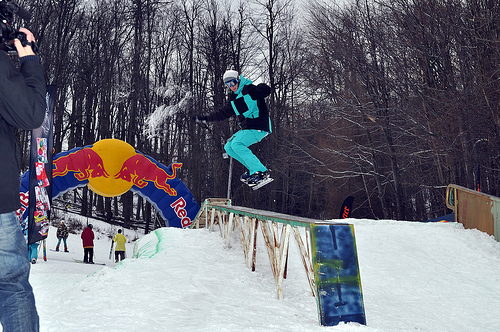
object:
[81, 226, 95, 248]
coat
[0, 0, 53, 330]
man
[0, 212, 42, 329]
jeans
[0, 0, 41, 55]
camera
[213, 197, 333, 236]
skateboarder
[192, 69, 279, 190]
man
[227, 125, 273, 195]
pants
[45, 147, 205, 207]
balloon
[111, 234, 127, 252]
coat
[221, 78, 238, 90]
glasses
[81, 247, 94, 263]
pants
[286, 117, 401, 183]
branches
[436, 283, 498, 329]
snow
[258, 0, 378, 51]
sky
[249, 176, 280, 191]
shadow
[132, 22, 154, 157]
tree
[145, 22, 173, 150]
tree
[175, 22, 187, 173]
tree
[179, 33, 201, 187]
tree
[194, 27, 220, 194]
tree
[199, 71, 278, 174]
suit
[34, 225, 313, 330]
ground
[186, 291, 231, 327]
snow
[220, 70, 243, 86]
cap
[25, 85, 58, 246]
cloth banner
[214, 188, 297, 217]
air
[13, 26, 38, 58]
hand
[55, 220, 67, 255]
people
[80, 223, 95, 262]
people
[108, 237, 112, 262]
skis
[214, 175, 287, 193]
snowboard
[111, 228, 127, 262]
people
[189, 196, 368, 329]
barrier